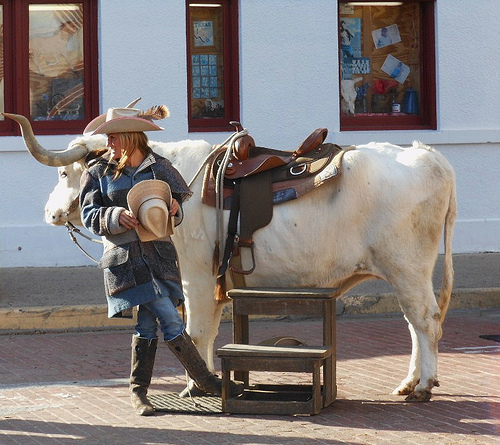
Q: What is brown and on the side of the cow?
A: Stool.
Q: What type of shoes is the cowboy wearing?
A: Boots.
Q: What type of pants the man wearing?
A: Jeans.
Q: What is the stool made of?
A: Wood.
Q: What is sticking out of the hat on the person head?
A: Feather.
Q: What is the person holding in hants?
A: Cowboy hat.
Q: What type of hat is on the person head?
A: Cowboy hat.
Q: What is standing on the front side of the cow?
A: A girl.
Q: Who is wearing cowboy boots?
A: The woman.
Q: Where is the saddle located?
A: On bull.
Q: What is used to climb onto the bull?
A: Wooden steps.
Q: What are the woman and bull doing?
A: Posing.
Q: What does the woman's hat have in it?
A: Feather.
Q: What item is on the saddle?
A: Rope.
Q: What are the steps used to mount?
A: The bull.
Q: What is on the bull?
A: Saddle.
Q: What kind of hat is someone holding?
A: Cowboy.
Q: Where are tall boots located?
A: Person's feet.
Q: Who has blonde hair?
A: The girl.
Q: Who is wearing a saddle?
A: The bull.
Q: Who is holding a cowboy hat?
A: The girl.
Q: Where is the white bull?
A: In the middle of a road.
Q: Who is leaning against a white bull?
A: A lady.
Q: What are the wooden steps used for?
A: To mount the bull.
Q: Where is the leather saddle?
A: On the bull.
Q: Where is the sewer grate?
A: In the middle of the road.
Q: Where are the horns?
A: On the bull's face.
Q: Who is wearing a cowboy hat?
A: A lady.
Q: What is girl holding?
A: Hat.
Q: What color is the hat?
A: Brown.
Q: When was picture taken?
A: Daytime.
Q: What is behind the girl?
A: Bull.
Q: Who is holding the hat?
A: Girl.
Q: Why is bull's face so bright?
A: Sun.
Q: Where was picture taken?
A: In front of the bull on the sidewalk.